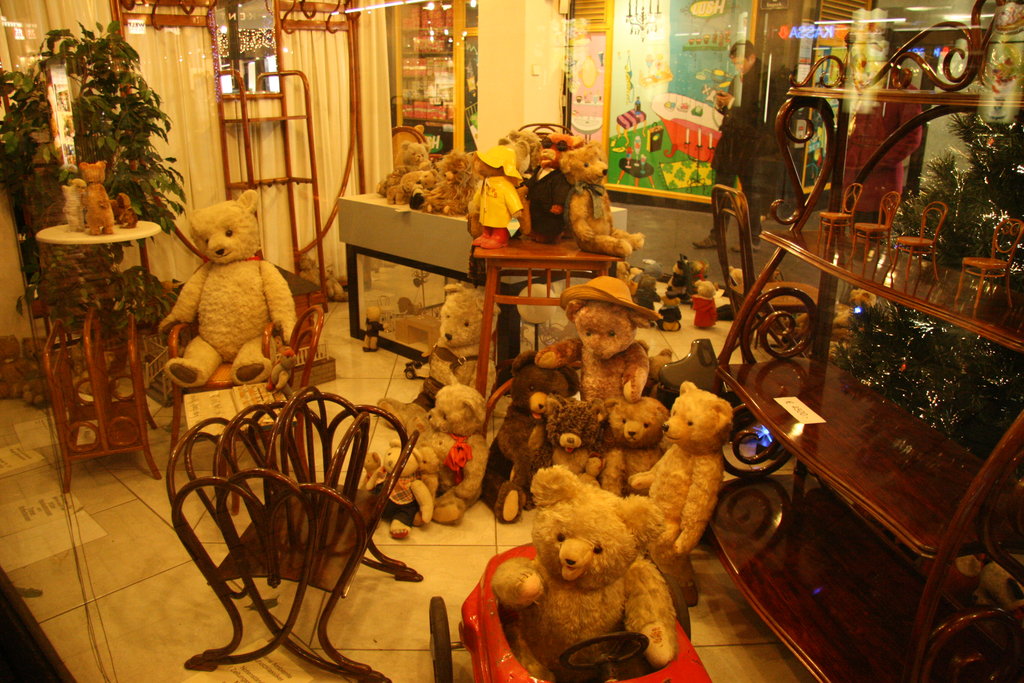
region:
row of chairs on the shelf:
[816, 167, 1020, 316]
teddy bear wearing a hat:
[554, 269, 660, 380]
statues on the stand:
[51, 158, 137, 250]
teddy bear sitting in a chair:
[140, 184, 295, 404]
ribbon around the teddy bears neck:
[440, 430, 476, 478]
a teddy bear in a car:
[527, 501, 649, 629]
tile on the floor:
[114, 517, 169, 615]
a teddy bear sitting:
[180, 216, 288, 360]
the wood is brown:
[841, 403, 919, 468]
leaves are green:
[113, 90, 172, 188]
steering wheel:
[559, 631, 645, 666]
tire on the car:
[420, 599, 471, 672]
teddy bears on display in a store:
[23, 22, 915, 624]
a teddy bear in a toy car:
[418, 477, 719, 680]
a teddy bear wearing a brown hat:
[555, 271, 664, 401]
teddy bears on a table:
[457, 133, 622, 307]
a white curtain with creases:
[280, 19, 391, 270]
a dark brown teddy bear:
[488, 356, 578, 530]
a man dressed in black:
[696, 40, 769, 228]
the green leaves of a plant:
[70, 26, 185, 217]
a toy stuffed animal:
[427, 458, 668, 680]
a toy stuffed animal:
[623, 392, 723, 564]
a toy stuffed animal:
[590, 383, 667, 510]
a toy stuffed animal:
[566, 292, 646, 410]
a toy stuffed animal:
[474, 374, 548, 523]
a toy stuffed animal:
[155, 193, 307, 381]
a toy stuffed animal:
[474, 148, 504, 244]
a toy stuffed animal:
[552, 143, 630, 265]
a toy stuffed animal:
[373, 140, 428, 198]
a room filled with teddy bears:
[125, 88, 786, 678]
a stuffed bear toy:
[149, 192, 324, 388]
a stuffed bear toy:
[498, 461, 667, 648]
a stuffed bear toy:
[654, 376, 727, 536]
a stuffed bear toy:
[606, 392, 673, 510]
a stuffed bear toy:
[544, 388, 606, 487]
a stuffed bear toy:
[479, 335, 581, 509]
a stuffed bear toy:
[544, 284, 666, 405]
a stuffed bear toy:
[432, 377, 494, 518]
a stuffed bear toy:
[408, 281, 519, 396]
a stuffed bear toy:
[561, 145, 654, 262]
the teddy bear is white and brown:
[166, 199, 296, 383]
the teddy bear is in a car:
[444, 492, 710, 679]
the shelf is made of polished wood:
[731, 348, 998, 548]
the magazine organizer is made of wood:
[43, 312, 158, 484]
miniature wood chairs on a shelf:
[804, 180, 1010, 308]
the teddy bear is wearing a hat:
[566, 272, 659, 353]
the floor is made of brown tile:
[16, 497, 188, 615]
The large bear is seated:
[156, 188, 294, 388]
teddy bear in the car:
[487, 466, 687, 678]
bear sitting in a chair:
[170, 184, 296, 481]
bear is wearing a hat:
[536, 264, 657, 399]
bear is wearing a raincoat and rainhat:
[464, 139, 520, 250]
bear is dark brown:
[474, 351, 564, 514]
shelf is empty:
[739, 340, 996, 545]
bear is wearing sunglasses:
[526, 121, 578, 165]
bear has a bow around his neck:
[561, 146, 623, 219]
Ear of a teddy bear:
[620, 486, 669, 547]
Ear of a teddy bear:
[522, 458, 576, 512]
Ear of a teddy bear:
[710, 394, 736, 430]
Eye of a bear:
[588, 534, 614, 566]